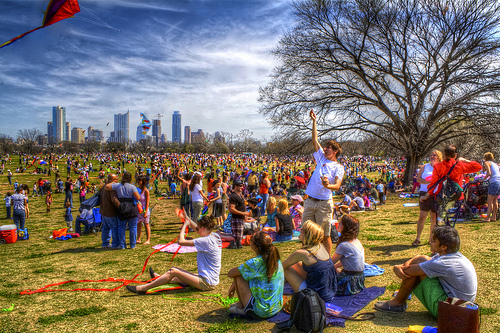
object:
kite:
[1, 0, 86, 47]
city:
[37, 101, 211, 149]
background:
[1, 101, 489, 151]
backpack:
[288, 286, 328, 332]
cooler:
[1, 223, 21, 245]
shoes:
[372, 300, 406, 316]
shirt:
[427, 160, 480, 202]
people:
[330, 212, 369, 296]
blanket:
[329, 285, 384, 324]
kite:
[138, 107, 153, 137]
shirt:
[237, 256, 286, 318]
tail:
[4, 26, 43, 47]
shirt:
[303, 147, 345, 200]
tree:
[261, 1, 499, 184]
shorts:
[228, 219, 248, 243]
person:
[372, 222, 479, 316]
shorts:
[412, 274, 448, 315]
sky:
[49, 23, 258, 110]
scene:
[3, 3, 499, 332]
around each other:
[96, 183, 121, 217]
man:
[301, 108, 345, 258]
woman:
[227, 229, 287, 320]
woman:
[411, 148, 441, 245]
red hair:
[444, 144, 458, 162]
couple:
[93, 171, 146, 251]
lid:
[0, 221, 17, 232]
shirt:
[189, 184, 204, 202]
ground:
[0, 253, 273, 333]